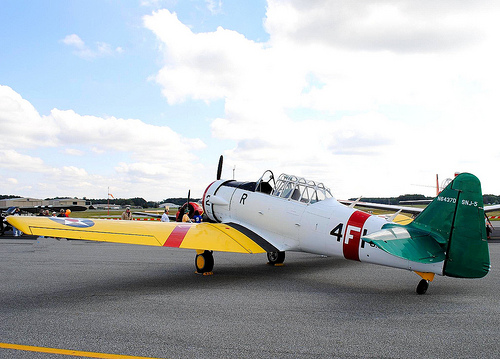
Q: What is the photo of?
A: A plane.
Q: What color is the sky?
A: Blue.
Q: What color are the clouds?
A: White.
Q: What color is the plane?
A: White, yellow and green.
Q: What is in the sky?
A: Clouds.